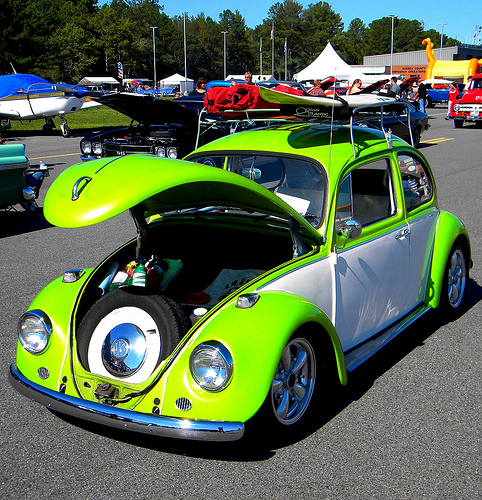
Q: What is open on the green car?
A: Hood.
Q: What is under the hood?
A: Tire.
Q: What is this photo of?
A: A street.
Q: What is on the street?
A: A car.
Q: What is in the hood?
A: A tire.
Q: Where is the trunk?
A: At the back of the car.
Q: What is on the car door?
A: A handle.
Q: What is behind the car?
A: A red truck.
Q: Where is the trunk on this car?
A: On the front.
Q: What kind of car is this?
A: Volkswagon.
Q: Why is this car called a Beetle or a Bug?
A: Because the car looks like a bug.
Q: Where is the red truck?
A: At the top right of the photo.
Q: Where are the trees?
A: Behind all the tents.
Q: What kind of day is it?
A: A clear blue day.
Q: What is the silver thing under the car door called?
A: The running board.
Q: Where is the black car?
A: Behind and to the left of the VW.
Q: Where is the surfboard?
A: On car.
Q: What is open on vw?
A: Front hood.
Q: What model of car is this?
A: Volkswagen Beetle.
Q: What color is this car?
A: Flourscent green.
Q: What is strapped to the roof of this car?
A: A surfboard.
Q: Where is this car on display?
A: A car show.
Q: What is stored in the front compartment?
A: A spare tire.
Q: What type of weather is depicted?
A: Sunny.